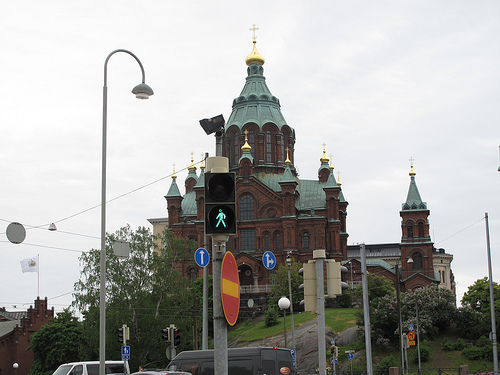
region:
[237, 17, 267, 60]
a white cross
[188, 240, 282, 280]
two blue round signs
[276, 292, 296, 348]
a white light on metal pole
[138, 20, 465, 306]
a building with crosses on all the points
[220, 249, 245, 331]
a round red and yellow sign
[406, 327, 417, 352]
sign that says to not turn left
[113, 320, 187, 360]
two street lights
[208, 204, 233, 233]
a green color person walking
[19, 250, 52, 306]
a white flag on top of a building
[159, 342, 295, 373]
a black van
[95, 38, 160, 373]
A tall light-post is in the foreground.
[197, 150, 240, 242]
A light is indicating that it is safe to cross the street.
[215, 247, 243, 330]
A red and yellow caution sign is attached to a pole.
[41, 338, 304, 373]
Two vehicles are parked in the foreground.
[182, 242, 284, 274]
Two blue and white signs are in the center of this photo.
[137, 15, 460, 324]
A large red building is in the background.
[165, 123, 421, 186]
Six yellow tops are visible with regard to this red building.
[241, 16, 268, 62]
A yellow cross is visible on the main structure of this red building.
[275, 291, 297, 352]
A white lamp-post is visible in the center of this photo.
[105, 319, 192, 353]
Traffic lights are near the parked vehicles.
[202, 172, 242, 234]
okay to cross now sign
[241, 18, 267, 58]
cross on top of steeple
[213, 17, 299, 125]
large steeple on top of old church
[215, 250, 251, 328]
yellow and red sign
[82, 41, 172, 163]
lamp post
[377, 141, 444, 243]
smaller steeple on church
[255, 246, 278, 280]
blue and white sign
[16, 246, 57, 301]
white flag flying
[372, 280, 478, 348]
green and white shrubbery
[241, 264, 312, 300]
white colored railing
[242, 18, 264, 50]
a cross on top of the spire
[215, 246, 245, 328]
the sign is red and yellow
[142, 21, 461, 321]
the building is red, green and tan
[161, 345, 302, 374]
a black van is in front of the building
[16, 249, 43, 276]
the flag is white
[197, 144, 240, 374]
the traffic signal has the walk sign lit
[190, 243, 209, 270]
the sign is blue and white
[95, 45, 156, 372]
the light pole is curved at the top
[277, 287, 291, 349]
the globe of the light is white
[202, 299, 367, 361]
the grass is green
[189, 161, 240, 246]
walk signal on crosswalk sign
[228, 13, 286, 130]
cross on top of building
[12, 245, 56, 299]
white flag on pole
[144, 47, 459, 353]
large building on a hill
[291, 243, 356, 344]
traffic signal on a pole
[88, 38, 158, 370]
large streetlamp on roadside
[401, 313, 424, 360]
no left turn sign on pole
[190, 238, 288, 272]
blue directional signs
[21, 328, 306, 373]
vehicles at cross street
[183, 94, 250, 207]
traffic camera on top of pole